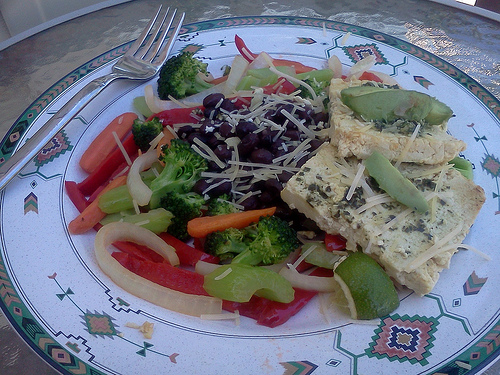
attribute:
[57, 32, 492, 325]
meal — mixed vegetable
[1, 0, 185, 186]
fork — head, stainless steel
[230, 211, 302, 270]
broccoli — piece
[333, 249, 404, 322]
lime piece — cut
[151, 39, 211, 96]
brocolli — piece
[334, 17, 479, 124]
plate — white, patterned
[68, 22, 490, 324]
food — colorful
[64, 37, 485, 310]
food — shredded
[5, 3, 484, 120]
table — silver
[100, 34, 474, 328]
meal — mixed vegetable